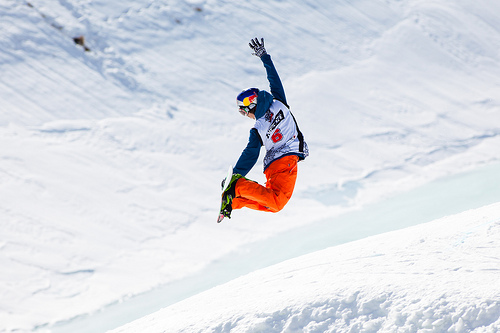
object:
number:
[268, 126, 287, 145]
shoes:
[215, 171, 243, 212]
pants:
[235, 154, 300, 212]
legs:
[235, 168, 297, 212]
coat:
[226, 53, 310, 180]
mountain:
[1, 25, 497, 287]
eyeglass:
[247, 103, 260, 113]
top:
[249, 94, 311, 172]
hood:
[253, 89, 272, 122]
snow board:
[216, 165, 235, 226]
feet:
[222, 172, 240, 207]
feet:
[221, 204, 232, 216]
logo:
[241, 95, 260, 107]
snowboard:
[217, 164, 239, 224]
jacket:
[218, 55, 310, 176]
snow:
[0, 0, 498, 330]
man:
[214, 34, 310, 223]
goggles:
[235, 106, 247, 115]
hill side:
[2, 0, 487, 196]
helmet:
[232, 88, 274, 120]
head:
[236, 88, 262, 118]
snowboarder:
[197, 55, 313, 285]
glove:
[246, 34, 265, 57]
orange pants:
[235, 154, 296, 211]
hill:
[30, 10, 166, 168]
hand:
[221, 172, 243, 195]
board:
[217, 171, 238, 225]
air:
[114, 51, 294, 203]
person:
[215, 54, 314, 186]